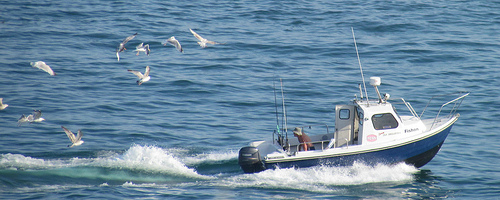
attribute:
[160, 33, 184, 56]
bird — sea gull, flying, looking, white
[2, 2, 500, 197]
water — calm, rough, blue, white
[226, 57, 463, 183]
boat — small, blue, moving fast, fast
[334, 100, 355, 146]
door — open